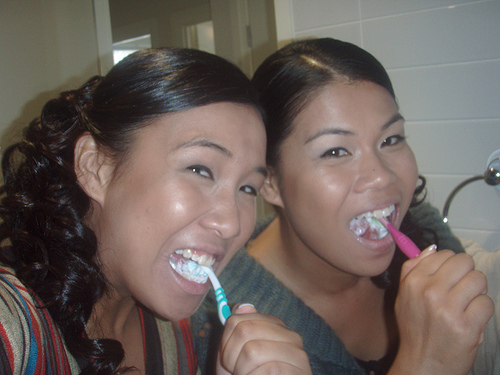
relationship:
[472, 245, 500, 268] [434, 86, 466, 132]
towel on wall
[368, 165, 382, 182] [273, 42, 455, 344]
mole on girl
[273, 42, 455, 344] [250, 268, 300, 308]
girl wearing sweater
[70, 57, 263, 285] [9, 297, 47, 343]
friend wearing shirt